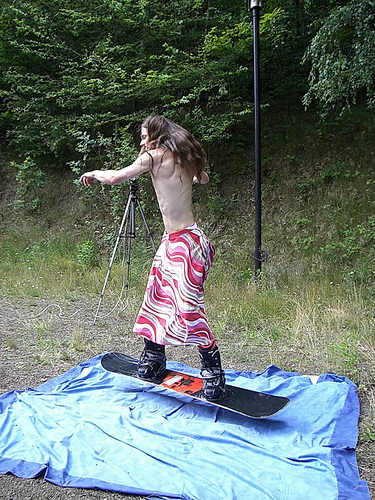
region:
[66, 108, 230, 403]
person posing in front of camera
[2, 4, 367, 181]
drooping and straight branches on trees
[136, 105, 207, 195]
long and dark hair flowing over back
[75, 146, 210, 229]
shirtless with bent elbows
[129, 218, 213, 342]
long skirt of red and pink swirls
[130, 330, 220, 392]
heavy black boots with black laces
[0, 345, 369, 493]
blue blanket with darker border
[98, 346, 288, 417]
black and orange skateboard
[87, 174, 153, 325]
black camera on tripod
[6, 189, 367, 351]
dirt, grasses and short plants on ground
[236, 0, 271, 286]
a pole, probably with a light on top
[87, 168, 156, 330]
a tripod, possibly w/ a camera on top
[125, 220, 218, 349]
a dude in a psychedelic pareo for no reason i can name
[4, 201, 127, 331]
cable coming from hidden camera leading into the nowhere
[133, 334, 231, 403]
board boots do not match the pareo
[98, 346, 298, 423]
board. looks like it's hovering. it's not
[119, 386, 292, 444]
either this shadow is 'shopped on, made from a wrinkle in the inexplicable blanket, or he's being held up by wires i cant see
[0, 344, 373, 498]
the inexplicable blanket [blue on blue]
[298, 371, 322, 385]
some kind of pad beneath the inexplicable blanket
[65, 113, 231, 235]
nice hair, dude, but the era of hair bands is long gone, & its people either sadder than you know or lost+gone themselves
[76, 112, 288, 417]
The young man is standing on a skateboard.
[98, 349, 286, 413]
The skateboard can apparently hover.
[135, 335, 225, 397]
The boots are glued to the skateboard.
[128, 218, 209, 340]
A pink skirt is around the man.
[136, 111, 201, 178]
The guy has very long hair.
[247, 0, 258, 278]
A long black electric pole in the woods.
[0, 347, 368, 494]
A blue towel is under the skateboard.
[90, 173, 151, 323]
A tripod is standing on the floor.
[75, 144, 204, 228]
The bare-chested man is skinny and muscular.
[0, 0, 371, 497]
The scene is happening in the woods.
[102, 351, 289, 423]
black and red snow board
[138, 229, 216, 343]
red and white skirt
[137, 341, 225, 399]
black snow boots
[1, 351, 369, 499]
blue tarp on ground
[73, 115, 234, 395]
man with no shirt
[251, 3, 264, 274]
black metal street lamp pole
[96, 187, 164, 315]
grey metal tripod on ground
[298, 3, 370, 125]
tree with green leaves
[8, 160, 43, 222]
green weeds on hill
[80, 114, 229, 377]
man standing on snowboard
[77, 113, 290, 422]
Man standing on a snowboard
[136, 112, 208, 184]
Man with long brown hair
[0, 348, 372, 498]
Blue cloth on the ground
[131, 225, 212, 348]
Wavy striped skirt on man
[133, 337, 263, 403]
Black snowboard boots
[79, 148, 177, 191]
Extended left arm of man.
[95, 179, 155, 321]
Tripod on the ground behind man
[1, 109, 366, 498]
Man riding snowboard on a blue blanket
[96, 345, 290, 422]
Black and orange snowboard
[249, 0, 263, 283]
Black steel post in ground